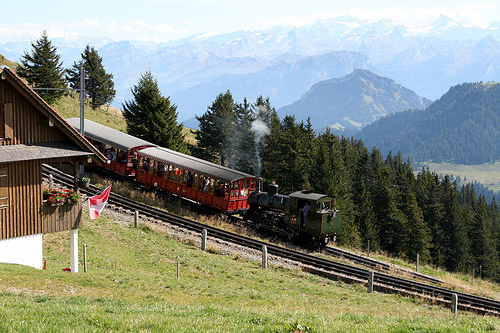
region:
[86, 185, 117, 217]
a flag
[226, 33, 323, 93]
the mountains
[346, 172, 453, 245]
the green trees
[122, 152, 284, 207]
the red train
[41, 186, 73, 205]
red flowers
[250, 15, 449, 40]
the snow on the mountain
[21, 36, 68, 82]
the tree on the hill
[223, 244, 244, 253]
small rocks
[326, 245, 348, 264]
the train tracks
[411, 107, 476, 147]
the green trees on the mountain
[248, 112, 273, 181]
a white puff of steam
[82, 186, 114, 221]
a red and white flag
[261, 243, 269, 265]
a wooden post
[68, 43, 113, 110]
a green pine tree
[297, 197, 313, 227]
the conductor of a train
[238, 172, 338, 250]
the train engine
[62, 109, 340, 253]
a red and green train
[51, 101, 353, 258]
a train going up a mountain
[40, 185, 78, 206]
red flowers in a window box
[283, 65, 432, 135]
a mountain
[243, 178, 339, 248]
a green train engine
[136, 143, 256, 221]
a red train passenger car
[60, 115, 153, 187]
a red train passenger car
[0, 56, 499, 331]
a steep grassy hillside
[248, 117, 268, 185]
a plume of steam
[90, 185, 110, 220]
a red and white flag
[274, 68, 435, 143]
a tall mountain in distance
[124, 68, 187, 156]
large green tree in distance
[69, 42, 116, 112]
large green tree in distance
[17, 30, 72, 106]
large green tree in distance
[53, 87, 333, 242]
train coming down on track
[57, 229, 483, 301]
track with no train on it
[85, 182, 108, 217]
flag hanging off terrace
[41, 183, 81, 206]
flowers hanging off terrace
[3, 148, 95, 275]
house on grass near rails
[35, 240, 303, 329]
green area near tracks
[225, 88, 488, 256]
row of trees on the landscape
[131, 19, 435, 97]
mountains in the distance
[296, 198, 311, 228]
person on the train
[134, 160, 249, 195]
people in the train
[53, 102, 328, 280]
train on the tracks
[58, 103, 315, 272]
train is red and black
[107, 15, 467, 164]
mountains behind the train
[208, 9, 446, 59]
snow on the mountains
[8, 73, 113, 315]
house near the train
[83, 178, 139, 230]
red and white flag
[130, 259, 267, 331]
grass is green and brown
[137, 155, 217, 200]
red car has windows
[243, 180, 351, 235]
engine is green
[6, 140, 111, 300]
building is brown and white